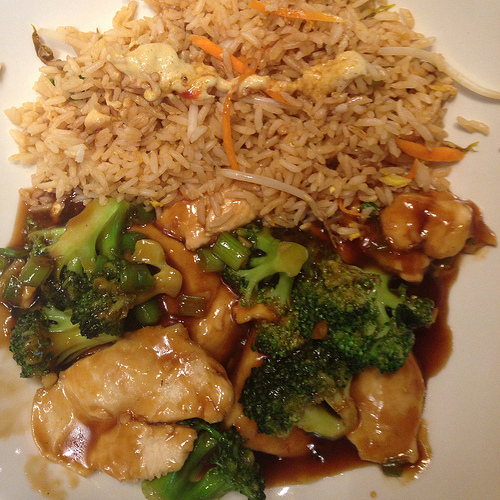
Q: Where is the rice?
A: Visible on the plate.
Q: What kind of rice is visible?
A: Fried rice.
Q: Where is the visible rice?
A: On a plate next the vegetables.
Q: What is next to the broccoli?
A: The visible rice.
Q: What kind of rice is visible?
A: Chinese.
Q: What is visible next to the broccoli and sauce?
A: Rice.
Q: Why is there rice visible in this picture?
A: It's an overview photo.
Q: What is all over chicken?
A: The sauce.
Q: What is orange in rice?
A: Carrots.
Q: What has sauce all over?
A: Broccoli.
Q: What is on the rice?
A: Sauce.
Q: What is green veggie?
A: Broccoli.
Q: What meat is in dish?
A: Chicken with sauce.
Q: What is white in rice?
A: The sprout.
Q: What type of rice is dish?
A: Off white rice.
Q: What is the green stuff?
A: Broccoli.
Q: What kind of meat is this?
A: Chicken.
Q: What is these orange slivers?
A: Carrots.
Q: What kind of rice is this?
A: White rice.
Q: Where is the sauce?
A: Mixed in the chicken and broccoli.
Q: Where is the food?
A: On a plate.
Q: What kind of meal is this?
A: A chinese dish.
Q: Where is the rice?
A: Beside the chicken and broccoli.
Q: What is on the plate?
A: Stir Fry.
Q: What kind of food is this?
A: Chinese.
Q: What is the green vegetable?
A: Broccoli.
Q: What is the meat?
A: Chicken.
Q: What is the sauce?
A: Teriyaki.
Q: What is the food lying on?
A: Table.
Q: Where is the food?
A: Plate.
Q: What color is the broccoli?
A: Green.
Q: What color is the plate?
A: White.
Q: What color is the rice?
A: Brown.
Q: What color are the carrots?
A: Orange.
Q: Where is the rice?
A: Above the broccoli.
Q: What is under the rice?
A: The broccoli.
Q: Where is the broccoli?
A: Under the rice.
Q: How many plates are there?
A: One.